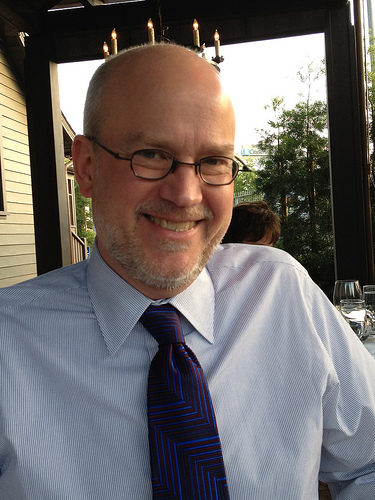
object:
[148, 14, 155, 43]
candle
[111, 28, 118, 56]
candle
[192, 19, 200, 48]
candle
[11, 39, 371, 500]
man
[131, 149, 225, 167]
eyes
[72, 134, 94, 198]
ear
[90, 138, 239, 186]
glasses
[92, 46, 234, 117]
bald head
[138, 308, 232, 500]
tie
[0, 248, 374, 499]
shirt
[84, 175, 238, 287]
beard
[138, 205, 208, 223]
moustache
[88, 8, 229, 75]
light fixture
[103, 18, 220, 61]
candles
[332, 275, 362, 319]
water glass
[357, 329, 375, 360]
table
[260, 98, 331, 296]
tree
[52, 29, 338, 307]
background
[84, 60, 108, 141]
hair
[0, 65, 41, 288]
siding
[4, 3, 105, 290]
building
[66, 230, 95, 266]
railing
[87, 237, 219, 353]
collar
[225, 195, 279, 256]
woman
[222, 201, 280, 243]
hair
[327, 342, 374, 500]
sleeves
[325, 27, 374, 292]
pole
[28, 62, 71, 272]
pole